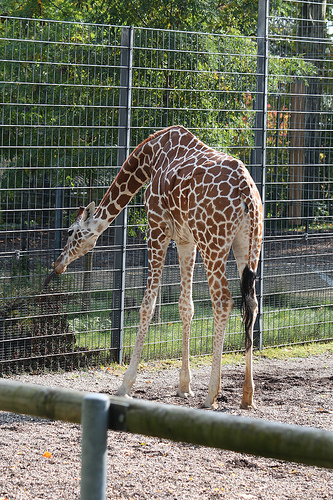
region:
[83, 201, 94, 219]
ear of a giraffe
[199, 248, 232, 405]
leg of a giraffe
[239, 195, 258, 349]
tail of a giraffe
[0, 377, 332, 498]
metal beams near camera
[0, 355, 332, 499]
dirt covering the ground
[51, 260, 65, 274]
snout of a giraffe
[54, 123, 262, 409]
a giraffe near the fence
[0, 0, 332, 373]
the fence is metal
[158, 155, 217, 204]
spots on the giraffe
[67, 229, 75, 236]
the eye is open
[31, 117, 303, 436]
giraffe standing on the dirt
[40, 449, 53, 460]
orange leaf on the ground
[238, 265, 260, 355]
long black hair on the tail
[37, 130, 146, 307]
neck is bent down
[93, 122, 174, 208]
hair along the back of the neck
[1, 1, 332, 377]
tall fence along the enclosure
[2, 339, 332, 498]
dirt on the ground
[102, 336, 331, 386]
grass along the fence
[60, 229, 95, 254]
brown spots on the face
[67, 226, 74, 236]
dark eye on the side of the face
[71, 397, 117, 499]
The pole is silver in color.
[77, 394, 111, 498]
The pole is made of metal.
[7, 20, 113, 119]
The fence is made of metal.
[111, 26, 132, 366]
The fence pole is tall.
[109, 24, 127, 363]
The fence poll is made of metal.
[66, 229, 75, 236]
The giraffe eye is black.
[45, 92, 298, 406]
this is a giraffe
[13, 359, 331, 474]
pole on a fence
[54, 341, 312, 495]
giraffe standing in dirt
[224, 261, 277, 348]
black hair on tail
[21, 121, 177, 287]
giraffe has head down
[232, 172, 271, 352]
tail of the giraffe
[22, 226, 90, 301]
giraffe sticking tongue out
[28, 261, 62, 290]
giraffe tongue is black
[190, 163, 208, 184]
spot on a giraffe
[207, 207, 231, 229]
spot on a giraffe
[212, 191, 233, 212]
spot on a giraffe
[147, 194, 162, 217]
spot on a giraffe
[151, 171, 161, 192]
spot on a giraffe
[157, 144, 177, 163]
spot on a giraffe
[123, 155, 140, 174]
spot on a giraffe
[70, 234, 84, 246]
spot on a giraffe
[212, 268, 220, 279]
spot on a giraffe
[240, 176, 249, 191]
spot on a giraffe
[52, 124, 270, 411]
Giraffe eating leaves through a fence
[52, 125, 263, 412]
Giraffe in pen at a zoo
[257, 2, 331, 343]
Metal animal enclosure fence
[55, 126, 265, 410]
Giraffe bending its neck down to eat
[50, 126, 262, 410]
Giraffe standing in pen eating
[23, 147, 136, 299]
Giraffe eating something through a fence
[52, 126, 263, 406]
Standing giraffe bending down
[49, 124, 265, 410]
Giraffe on display in a zoo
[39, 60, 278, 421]
Giraffe standing by a fence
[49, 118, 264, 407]
giraffe standing in the ground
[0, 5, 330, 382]
gray metal fence behind big giraffe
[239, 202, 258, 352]
large black hairy tail of giraffe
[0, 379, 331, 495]
wooden pole behind giraffe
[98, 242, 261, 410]
four legs of giraffe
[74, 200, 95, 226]
two small ears of big giraffe